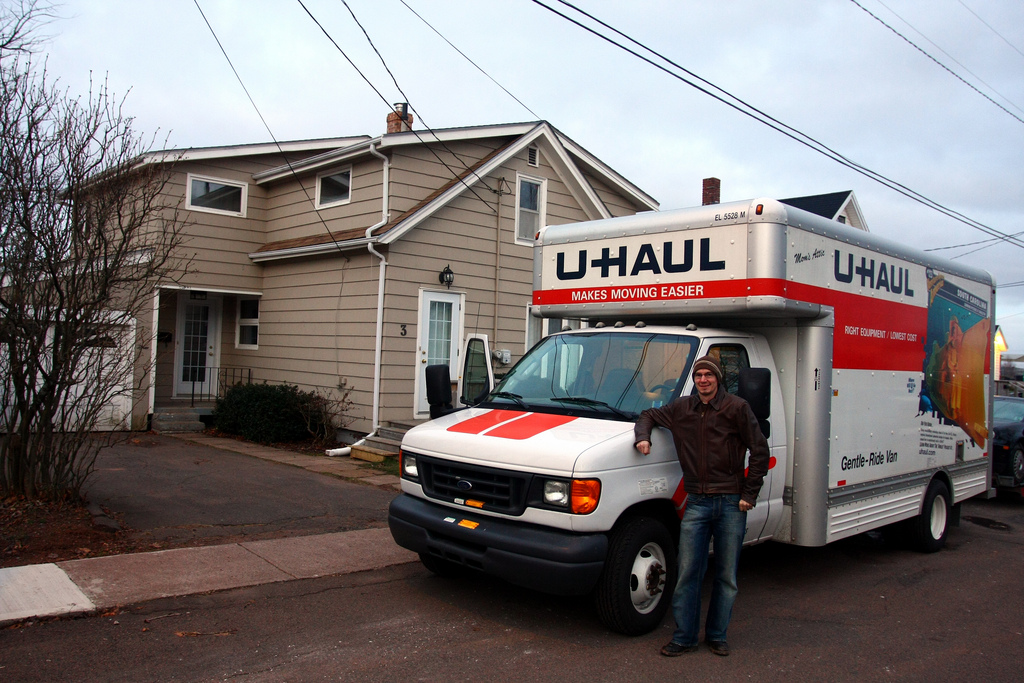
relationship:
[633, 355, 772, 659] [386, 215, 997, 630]
person leaning on uhaul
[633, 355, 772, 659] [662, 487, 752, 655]
person wearing jeans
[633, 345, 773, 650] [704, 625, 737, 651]
person wearing shoe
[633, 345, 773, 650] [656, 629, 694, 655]
person wearing shoe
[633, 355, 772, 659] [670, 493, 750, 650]
person wearing jeans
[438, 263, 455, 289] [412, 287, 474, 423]
light above door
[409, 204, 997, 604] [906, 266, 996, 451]
uhaul has picture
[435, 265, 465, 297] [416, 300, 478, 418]
light above door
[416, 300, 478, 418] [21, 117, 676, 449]
door on house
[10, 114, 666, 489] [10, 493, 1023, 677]
house by road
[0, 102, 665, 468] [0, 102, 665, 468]
house with house